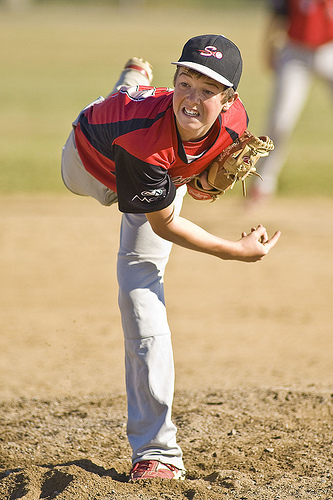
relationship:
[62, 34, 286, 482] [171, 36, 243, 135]
boy has head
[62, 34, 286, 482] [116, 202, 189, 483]
boy has leg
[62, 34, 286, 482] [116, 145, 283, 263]
boy has arm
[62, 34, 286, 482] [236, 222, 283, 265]
boy has hand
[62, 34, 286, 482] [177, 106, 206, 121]
boy has mouth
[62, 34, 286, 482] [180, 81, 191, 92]
boy has eye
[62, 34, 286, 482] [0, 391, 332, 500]
boy on mound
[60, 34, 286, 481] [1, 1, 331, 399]
boy in infield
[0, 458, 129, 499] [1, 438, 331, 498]
shadow on dirt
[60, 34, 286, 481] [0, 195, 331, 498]
boy on ground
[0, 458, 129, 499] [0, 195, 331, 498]
shadow on ground